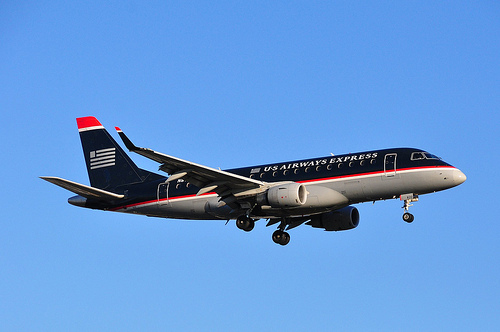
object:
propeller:
[252, 182, 311, 208]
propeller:
[304, 206, 362, 231]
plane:
[64, 108, 473, 241]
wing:
[114, 126, 256, 185]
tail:
[63, 115, 141, 197]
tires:
[271, 230, 286, 244]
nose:
[440, 161, 474, 192]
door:
[382, 153, 397, 179]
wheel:
[399, 212, 417, 223]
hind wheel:
[234, 215, 255, 233]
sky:
[262, 22, 354, 41]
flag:
[73, 137, 125, 175]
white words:
[262, 160, 287, 171]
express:
[328, 152, 379, 164]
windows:
[260, 171, 268, 177]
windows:
[406, 149, 447, 163]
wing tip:
[114, 125, 137, 152]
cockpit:
[401, 149, 452, 174]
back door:
[155, 180, 171, 206]